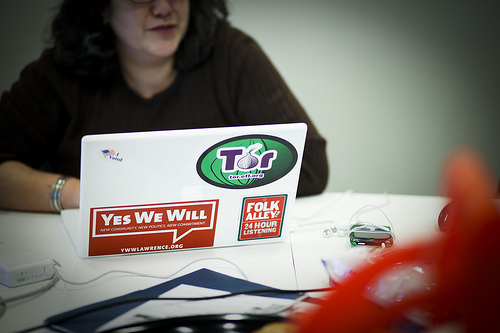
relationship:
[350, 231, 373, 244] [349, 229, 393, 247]
part of a box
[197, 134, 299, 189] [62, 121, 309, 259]
sticker on laptop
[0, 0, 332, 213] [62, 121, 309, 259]
woman working on laptop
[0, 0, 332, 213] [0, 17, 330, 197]
woman wearing shirt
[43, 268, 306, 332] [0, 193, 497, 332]
booklet on table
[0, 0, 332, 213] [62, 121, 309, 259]
woman on laptop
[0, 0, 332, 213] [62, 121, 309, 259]
woman on a laptop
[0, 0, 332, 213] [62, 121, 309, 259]
woman on a white laptop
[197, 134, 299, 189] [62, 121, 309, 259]
sticker on back of laptop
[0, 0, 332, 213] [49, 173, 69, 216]
woman wearing a bracelet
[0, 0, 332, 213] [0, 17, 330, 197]
woman wearing a shirt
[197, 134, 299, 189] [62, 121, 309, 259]
sticker covering laptop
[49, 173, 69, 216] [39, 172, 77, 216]
bracelet on wrist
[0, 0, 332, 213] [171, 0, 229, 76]
woman has hair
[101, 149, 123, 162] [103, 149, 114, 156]
sticker with flag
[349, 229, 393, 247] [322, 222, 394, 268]
iphone with headphones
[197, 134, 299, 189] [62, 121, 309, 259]
sticker on a laptop